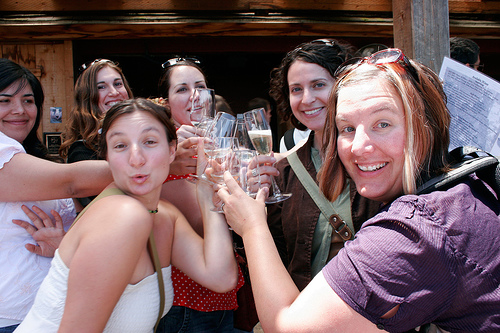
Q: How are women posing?
A: In a group.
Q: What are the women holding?
A: Champagne glasses.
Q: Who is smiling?
A: All the women.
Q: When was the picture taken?
A: During daytime.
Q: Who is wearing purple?
A: Woman on right.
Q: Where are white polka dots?
A: On red shirt.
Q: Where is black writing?
A: On white sign.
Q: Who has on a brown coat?
A: Second woman from the right.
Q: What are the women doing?
A: Toasting champagne.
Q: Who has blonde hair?
A: The person on the right.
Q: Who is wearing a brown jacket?
A: The woman in the middle right.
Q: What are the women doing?
A: Partying.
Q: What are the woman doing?
A: Holding up glasses.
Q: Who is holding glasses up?
A: Six women.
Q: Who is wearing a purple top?
A: The woman on the right.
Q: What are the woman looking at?
A: The camera.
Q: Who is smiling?
A: All of the women.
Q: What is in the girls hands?
A: Wineglasses.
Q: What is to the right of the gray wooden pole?
A: Head.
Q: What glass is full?
A: Far right glass.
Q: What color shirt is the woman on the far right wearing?
A: Purple.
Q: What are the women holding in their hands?
A: Champagne flutes.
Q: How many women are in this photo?
A: Six.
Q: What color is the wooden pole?
A: Brown.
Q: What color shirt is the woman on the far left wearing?
A: White.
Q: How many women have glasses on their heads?
A: Four.